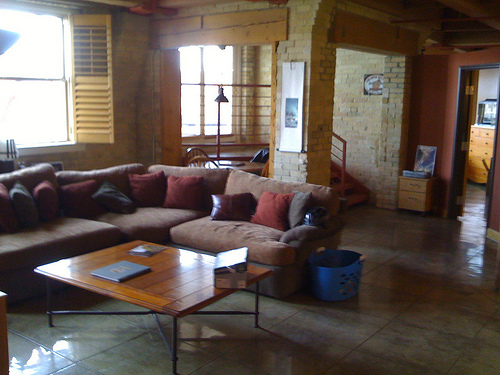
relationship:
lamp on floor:
[209, 86, 235, 170] [1, 186, 499, 369]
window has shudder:
[1, 5, 92, 150] [67, 12, 113, 145]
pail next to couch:
[302, 240, 370, 309] [4, 163, 342, 306]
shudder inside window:
[67, 12, 113, 145] [1, 5, 92, 150]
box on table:
[215, 242, 251, 293] [39, 236, 276, 373]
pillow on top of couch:
[209, 186, 256, 223] [4, 163, 342, 306]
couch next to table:
[4, 163, 342, 306] [39, 236, 276, 373]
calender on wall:
[279, 60, 307, 153] [0, 3, 411, 217]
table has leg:
[39, 236, 276, 373] [39, 273, 65, 335]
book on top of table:
[90, 257, 153, 284] [39, 236, 276, 373]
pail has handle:
[302, 240, 370, 309] [314, 246, 326, 254]